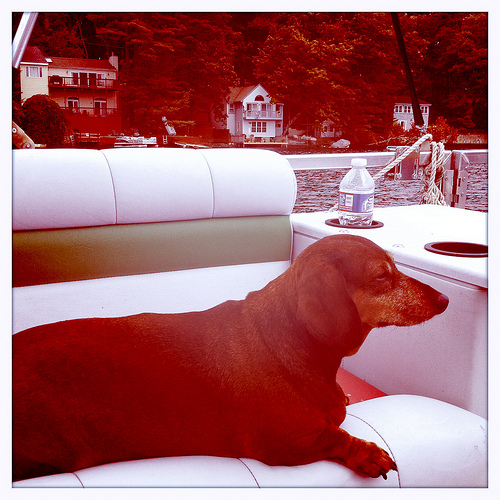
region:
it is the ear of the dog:
[300, 270, 367, 342]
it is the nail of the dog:
[371, 462, 386, 474]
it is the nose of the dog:
[431, 290, 442, 310]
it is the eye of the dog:
[367, 261, 392, 286]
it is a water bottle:
[334, 156, 379, 224]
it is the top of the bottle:
[351, 155, 366, 167]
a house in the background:
[230, 80, 280, 139]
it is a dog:
[12, 230, 432, 482]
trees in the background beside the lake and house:
[263, 15, 338, 101]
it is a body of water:
[303, 177, 327, 204]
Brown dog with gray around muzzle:
[8, 232, 450, 477]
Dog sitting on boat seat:
[16, 144, 485, 484]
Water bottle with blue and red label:
[329, 152, 379, 226]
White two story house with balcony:
[219, 80, 287, 145]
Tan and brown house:
[15, 40, 127, 140]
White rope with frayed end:
[329, 133, 451, 205]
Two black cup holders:
[316, 195, 485, 257]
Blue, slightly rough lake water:
[277, 151, 488, 214]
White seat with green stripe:
[17, 140, 481, 480]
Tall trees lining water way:
[16, 25, 491, 205]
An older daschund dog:
[15, 225, 431, 481]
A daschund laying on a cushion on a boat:
[18, 230, 447, 494]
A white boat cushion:
[48, 433, 474, 488]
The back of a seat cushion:
[15, 141, 280, 291]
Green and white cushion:
[20, 151, 255, 291]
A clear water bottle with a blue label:
[337, 137, 372, 227]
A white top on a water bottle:
[324, 156, 380, 216]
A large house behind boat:
[15, 35, 127, 146]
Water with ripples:
[301, 160, 337, 208]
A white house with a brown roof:
[217, 70, 300, 140]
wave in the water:
[301, 185, 319, 198]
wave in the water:
[312, 168, 326, 178]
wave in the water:
[473, 188, 480, 197]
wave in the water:
[398, 190, 408, 199]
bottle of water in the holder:
[331, 155, 376, 228]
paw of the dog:
[349, 446, 404, 486]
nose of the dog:
[396, 283, 459, 343]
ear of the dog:
[306, 295, 362, 362]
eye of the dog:
[363, 262, 398, 294]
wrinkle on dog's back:
[237, 329, 283, 372]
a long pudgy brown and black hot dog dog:
[14, 235, 448, 477]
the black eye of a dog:
[372, 264, 389, 283]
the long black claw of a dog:
[379, 470, 387, 480]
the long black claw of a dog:
[386, 459, 396, 471]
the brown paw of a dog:
[340, 436, 393, 478]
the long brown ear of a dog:
[300, 261, 361, 343]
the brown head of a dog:
[297, 237, 447, 344]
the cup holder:
[427, 241, 487, 261]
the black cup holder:
[326, 213, 385, 229]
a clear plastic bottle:
[339, 159, 372, 228]